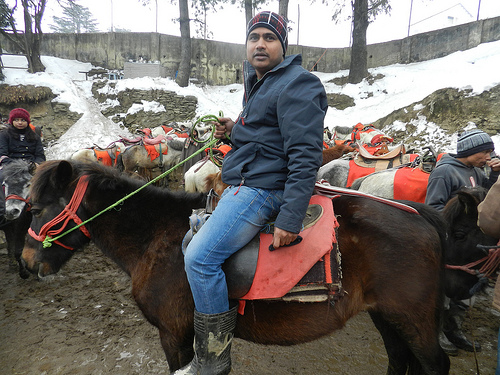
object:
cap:
[245, 11, 289, 51]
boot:
[438, 296, 458, 357]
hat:
[454, 128, 495, 159]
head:
[455, 128, 493, 167]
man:
[424, 126, 499, 355]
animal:
[115, 135, 185, 183]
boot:
[172, 303, 239, 373]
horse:
[19, 158, 450, 373]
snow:
[2, 36, 500, 166]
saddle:
[181, 187, 342, 316]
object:
[267, 233, 303, 251]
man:
[172, 10, 327, 375]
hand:
[270, 226, 298, 249]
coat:
[222, 52, 328, 233]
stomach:
[233, 303, 359, 347]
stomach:
[228, 123, 256, 182]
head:
[7, 107, 29, 129]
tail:
[397, 200, 452, 342]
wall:
[73, 33, 146, 59]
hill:
[91, 80, 169, 124]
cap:
[8, 108, 30, 126]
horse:
[0, 156, 38, 279]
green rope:
[42, 110, 231, 248]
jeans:
[184, 184, 284, 314]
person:
[0, 107, 45, 167]